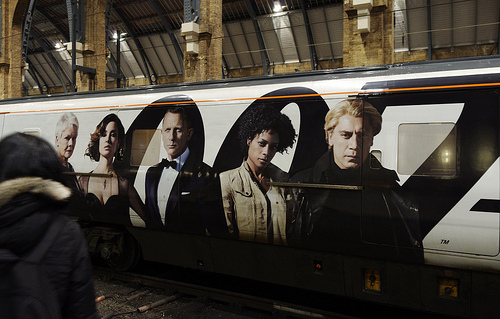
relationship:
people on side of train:
[54, 97, 429, 267] [2, 56, 496, 314]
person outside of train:
[0, 125, 93, 312] [2, 56, 496, 314]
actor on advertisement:
[212, 108, 309, 249] [24, 88, 455, 293]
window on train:
[396, 122, 457, 177] [2, 56, 496, 314]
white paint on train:
[9, 106, 53, 130] [11, 58, 495, 274]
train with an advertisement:
[2, 56, 496, 314] [52, 72, 499, 266]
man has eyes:
[139, 101, 230, 235] [164, 125, 183, 135]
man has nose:
[284, 97, 424, 260] [348, 134, 359, 149]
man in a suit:
[144, 108, 224, 231] [145, 146, 225, 229]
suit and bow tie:
[145, 146, 225, 229] [161, 156, 176, 166]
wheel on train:
[88, 216, 143, 274] [11, 58, 495, 274]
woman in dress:
[74, 113, 149, 256] [74, 170, 127, 241]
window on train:
[394, 118, 457, 178] [2, 56, 496, 314]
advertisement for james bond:
[2, 61, 499, 277] [6, 69, 498, 270]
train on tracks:
[0, 56, 499, 319] [1, 260, 493, 316]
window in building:
[222, 7, 318, 74] [1, 0, 499, 81]